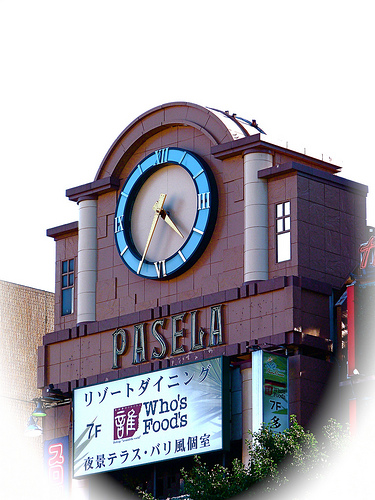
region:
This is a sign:
[100, 267, 274, 490]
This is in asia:
[69, 330, 270, 492]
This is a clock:
[124, 171, 364, 298]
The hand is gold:
[152, 220, 194, 290]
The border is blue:
[121, 159, 146, 227]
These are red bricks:
[52, 255, 193, 433]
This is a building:
[38, 141, 373, 363]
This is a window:
[276, 147, 356, 288]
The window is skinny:
[236, 193, 293, 366]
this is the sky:
[21, 103, 70, 175]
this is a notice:
[87, 373, 219, 454]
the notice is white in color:
[196, 388, 208, 416]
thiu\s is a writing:
[143, 396, 184, 429]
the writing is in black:
[145, 400, 191, 431]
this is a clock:
[119, 176, 198, 256]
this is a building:
[82, 152, 373, 358]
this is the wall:
[219, 216, 239, 282]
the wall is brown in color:
[219, 226, 240, 279]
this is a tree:
[189, 467, 239, 491]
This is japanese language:
[75, 370, 237, 484]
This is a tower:
[225, 238, 345, 422]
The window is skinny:
[261, 206, 296, 260]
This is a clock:
[107, 182, 224, 313]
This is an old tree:
[229, 415, 305, 485]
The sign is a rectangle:
[81, 375, 248, 495]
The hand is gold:
[111, 222, 195, 323]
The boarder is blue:
[63, 153, 243, 258]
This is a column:
[226, 220, 273, 262]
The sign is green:
[240, 342, 293, 466]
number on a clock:
[152, 145, 172, 166]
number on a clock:
[192, 189, 215, 212]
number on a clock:
[151, 256, 169, 279]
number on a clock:
[110, 212, 128, 235]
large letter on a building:
[203, 301, 229, 349]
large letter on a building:
[188, 303, 206, 356]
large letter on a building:
[167, 307, 189, 358]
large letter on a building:
[148, 313, 169, 361]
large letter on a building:
[131, 316, 149, 365]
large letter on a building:
[107, 322, 131, 371]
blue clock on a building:
[106, 142, 217, 285]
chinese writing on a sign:
[69, 355, 241, 475]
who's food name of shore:
[141, 394, 190, 431]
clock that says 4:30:
[107, 153, 213, 281]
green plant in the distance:
[175, 413, 340, 491]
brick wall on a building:
[3, 282, 26, 441]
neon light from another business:
[359, 231, 372, 269]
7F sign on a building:
[262, 352, 284, 432]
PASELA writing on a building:
[102, 307, 233, 364]